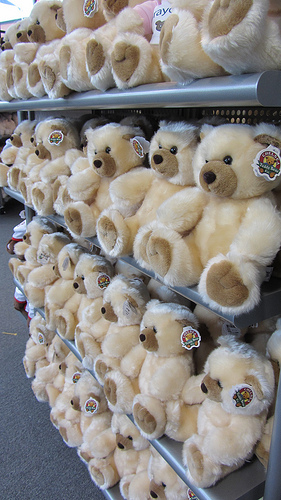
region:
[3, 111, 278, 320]
several stuffed bears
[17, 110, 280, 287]
stuffed bears on a shelf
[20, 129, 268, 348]
stuffed bears in a store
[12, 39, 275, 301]
stuffed bears for sale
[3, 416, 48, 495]
the carpet on a floor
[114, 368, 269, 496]
a shelf holding up some bears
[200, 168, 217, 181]
a stuffed bear's nose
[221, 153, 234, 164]
a stuffed bear's eye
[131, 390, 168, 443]
a stuffed bear's foot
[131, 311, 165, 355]
a stuffed bear's face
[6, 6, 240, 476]
teddy bears on the shelf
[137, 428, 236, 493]
the shelf is silver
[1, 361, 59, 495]
the floor is carpeted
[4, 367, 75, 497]
the carpet is gray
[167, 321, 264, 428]
tags on bears' ear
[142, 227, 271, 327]
the feet are brown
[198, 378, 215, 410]
the nose is black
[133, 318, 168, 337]
the eyes are black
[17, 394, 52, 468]
the carpet is gray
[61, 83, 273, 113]
the shelf is silver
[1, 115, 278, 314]
A shelf of stuffed teddy bears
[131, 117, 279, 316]
Tan colored teddy bear with a brown nose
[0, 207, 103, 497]
Gray carpet on the floor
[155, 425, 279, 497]
Gray metal shelf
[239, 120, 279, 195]
Tag on a stuffed bears ear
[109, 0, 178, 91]
Teddy bear with a shirt on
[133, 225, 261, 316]
Two stuffed teddy bear paws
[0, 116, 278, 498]
Three shelves with the same bears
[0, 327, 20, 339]
Yellow strip on the floor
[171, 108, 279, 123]
Holes in metal shelving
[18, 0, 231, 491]
shelves of bears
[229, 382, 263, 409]
tag on ear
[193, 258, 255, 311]
paw on bear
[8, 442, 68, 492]
gray carpet on floor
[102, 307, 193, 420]
cream color bear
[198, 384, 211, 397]
black nose on bear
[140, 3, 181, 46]
pink white and blue shirt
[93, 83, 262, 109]
metal shelfing under bears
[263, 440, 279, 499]
a steel pole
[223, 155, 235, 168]
a bears eye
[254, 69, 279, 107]
edge of the shelf where stuffed teddy bears are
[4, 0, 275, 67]
row of stuffed teddy bears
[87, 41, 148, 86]
bottom of feet of stuff teddy bears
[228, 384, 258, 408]
label and tag of stuff teddy bear maker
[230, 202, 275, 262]
arm of stuff teddy bear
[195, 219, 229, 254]
belly of stuff teddy bear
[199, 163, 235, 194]
nose and mouth of stuff teddy bear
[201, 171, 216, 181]
nose of stuff teddy bear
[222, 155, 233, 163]
eye of stuff teddy bear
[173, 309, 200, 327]
ear of stuff teddy bear